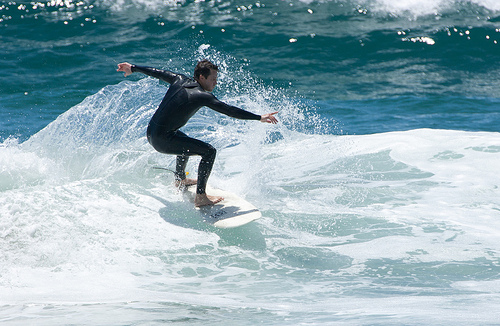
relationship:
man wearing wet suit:
[108, 44, 273, 194] [145, 63, 240, 175]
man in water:
[108, 44, 273, 194] [367, 120, 408, 152]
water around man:
[367, 120, 408, 152] [108, 44, 273, 194]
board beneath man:
[211, 209, 269, 237] [108, 44, 273, 194]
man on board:
[108, 44, 273, 194] [211, 209, 269, 237]